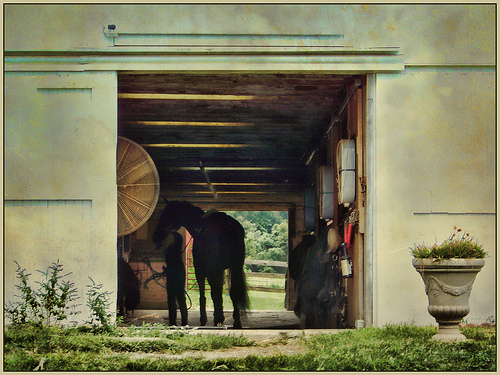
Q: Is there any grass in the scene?
A: Yes, there is grass.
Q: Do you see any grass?
A: Yes, there is grass.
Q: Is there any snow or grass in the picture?
A: Yes, there is grass.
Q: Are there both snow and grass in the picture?
A: No, there is grass but no snow.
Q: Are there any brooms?
A: No, there are no brooms.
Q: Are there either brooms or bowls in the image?
A: No, there are no brooms or bowls.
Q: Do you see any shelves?
A: No, there are no shelves.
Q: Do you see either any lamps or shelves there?
A: No, there are no shelves or lamps.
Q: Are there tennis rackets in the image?
A: No, there are no tennis rackets.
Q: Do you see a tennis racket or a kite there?
A: No, there are no rackets or kites.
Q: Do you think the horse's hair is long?
A: Yes, the hair is long.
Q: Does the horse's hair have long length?
A: Yes, the hair is long.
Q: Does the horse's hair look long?
A: Yes, the hair is long.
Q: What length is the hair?
A: The hair is long.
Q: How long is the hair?
A: The hair is long.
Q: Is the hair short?
A: No, the hair is long.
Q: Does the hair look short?
A: No, the hair is long.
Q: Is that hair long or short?
A: The hair is long.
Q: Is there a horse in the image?
A: Yes, there is a horse.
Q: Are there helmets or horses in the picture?
A: Yes, there is a horse.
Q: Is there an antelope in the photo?
A: No, there are no antelopes.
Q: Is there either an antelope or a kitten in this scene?
A: No, there are no antelopes or kittens.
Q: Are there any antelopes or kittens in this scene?
A: No, there are no antelopes or kittens.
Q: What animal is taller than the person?
A: The horse is taller than the person.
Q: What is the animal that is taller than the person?
A: The animal is a horse.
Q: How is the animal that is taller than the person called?
A: The animal is a horse.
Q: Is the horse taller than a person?
A: Yes, the horse is taller than a person.